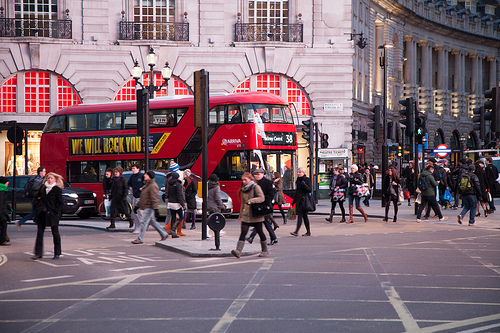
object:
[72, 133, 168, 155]
sign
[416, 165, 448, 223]
man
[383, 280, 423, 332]
white stripe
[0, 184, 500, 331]
street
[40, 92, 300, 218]
bus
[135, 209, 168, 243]
jeans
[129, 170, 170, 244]
man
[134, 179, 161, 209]
jacket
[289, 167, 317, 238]
woman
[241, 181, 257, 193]
scarf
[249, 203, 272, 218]
purse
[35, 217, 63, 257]
pants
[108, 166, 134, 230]
woman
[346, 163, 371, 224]
woman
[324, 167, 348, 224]
woman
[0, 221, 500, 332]
crosswalk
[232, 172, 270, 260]
woman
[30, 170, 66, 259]
woman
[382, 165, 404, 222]
woman